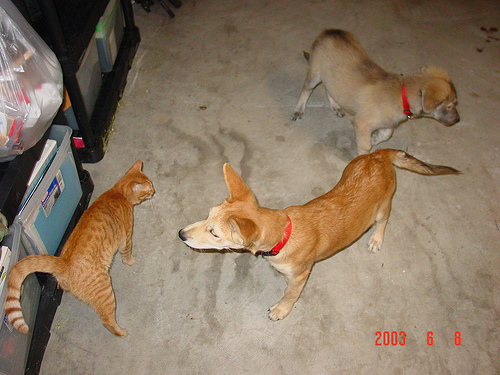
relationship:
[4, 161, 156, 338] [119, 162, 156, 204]
cat has a head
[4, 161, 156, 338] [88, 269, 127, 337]
cat has a leg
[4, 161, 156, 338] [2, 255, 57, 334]
cat has a tail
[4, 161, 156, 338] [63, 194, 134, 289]
cat has a body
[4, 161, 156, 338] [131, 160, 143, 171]
cat has an ear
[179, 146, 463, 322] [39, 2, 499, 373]
dog on floor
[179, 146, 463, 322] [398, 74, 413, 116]
dog has a collar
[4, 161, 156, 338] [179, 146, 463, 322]
cat next to a dog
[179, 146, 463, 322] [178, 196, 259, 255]
dog has a head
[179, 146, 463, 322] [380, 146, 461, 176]
dog has a tail